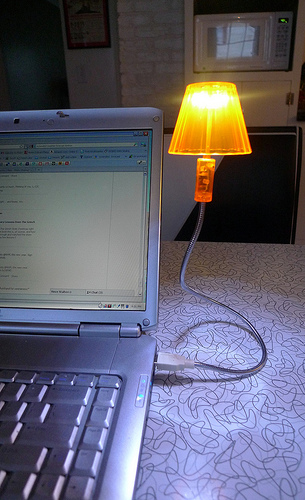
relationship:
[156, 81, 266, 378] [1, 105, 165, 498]
lamp next to laptop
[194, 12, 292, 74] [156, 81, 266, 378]
microwave behind lamp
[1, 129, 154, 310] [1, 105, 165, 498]
screen on laptop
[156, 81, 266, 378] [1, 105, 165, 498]
lamp plugged into laptop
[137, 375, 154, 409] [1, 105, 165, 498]
lights on laptop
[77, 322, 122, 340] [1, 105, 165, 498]
hinge on laptop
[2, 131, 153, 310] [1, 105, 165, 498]
icons on laptop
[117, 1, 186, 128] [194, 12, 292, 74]
bricks near microwave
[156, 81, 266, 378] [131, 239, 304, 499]
lamp on surface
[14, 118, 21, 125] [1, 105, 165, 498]
camera on laptop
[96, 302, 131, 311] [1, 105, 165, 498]
icons on laptop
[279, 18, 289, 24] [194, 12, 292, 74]
green lights on microwave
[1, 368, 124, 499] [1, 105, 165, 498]
keyboard on laptop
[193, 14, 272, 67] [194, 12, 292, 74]
reflection on microwave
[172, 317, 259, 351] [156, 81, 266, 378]
shadow from lamp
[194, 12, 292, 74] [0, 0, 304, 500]
microwave in room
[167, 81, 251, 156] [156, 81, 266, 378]
shade on lamp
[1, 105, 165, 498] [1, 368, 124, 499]
laptop has a keyboard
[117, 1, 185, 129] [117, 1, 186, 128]
wall made of bricks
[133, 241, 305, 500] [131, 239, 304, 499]
boomerangs on surface